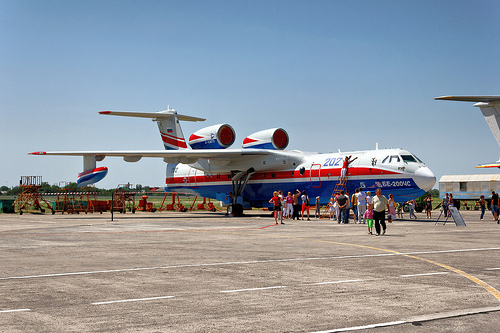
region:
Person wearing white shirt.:
[369, 196, 391, 209]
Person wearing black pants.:
[375, 215, 392, 230]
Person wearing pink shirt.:
[362, 208, 374, 215]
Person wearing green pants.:
[356, 215, 373, 237]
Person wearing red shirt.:
[267, 186, 292, 230]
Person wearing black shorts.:
[266, 198, 288, 214]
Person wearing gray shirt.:
[335, 192, 350, 204]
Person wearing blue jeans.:
[334, 198, 351, 224]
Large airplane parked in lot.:
[133, 113, 421, 221]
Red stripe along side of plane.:
[218, 160, 382, 186]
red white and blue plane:
[59, 105, 455, 218]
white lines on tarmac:
[73, 215, 419, 330]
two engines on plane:
[181, 105, 304, 162]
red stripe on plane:
[196, 157, 420, 192]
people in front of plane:
[261, 184, 461, 251]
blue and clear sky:
[184, 20, 344, 79]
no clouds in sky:
[122, 17, 372, 112]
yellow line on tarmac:
[337, 230, 455, 331]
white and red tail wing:
[110, 98, 189, 142]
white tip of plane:
[398, 157, 438, 189]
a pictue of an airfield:
[27, 82, 495, 240]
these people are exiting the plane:
[250, 172, 409, 219]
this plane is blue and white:
[26, 103, 428, 184]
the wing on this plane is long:
[23, 123, 313, 175]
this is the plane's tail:
[100, 90, 210, 147]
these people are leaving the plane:
[264, 151, 447, 230]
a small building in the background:
[435, 170, 498, 215]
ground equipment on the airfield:
[10, 171, 195, 211]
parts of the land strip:
[9, 218, 482, 313]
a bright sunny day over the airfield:
[14, 33, 492, 253]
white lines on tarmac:
[85, 261, 327, 330]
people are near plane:
[274, 185, 451, 242]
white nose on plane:
[410, 167, 438, 202]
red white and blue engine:
[171, 115, 261, 162]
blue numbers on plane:
[314, 150, 381, 175]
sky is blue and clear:
[68, 12, 233, 114]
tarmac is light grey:
[62, 230, 280, 327]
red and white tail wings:
[90, 101, 209, 145]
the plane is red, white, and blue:
[73, 97, 451, 227]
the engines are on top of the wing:
[188, 100, 307, 167]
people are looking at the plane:
[257, 172, 449, 247]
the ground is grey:
[83, 227, 368, 314]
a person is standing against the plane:
[325, 151, 369, 181]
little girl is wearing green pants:
[351, 201, 377, 233]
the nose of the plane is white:
[400, 160, 442, 191]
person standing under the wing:
[182, 180, 251, 231]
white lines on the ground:
[117, 255, 409, 322]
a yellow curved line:
[8, 211, 482, 311]